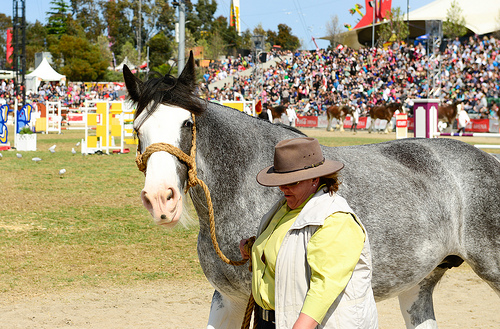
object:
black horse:
[120, 49, 499, 329]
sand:
[97, 296, 191, 317]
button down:
[240, 187, 381, 328]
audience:
[0, 34, 498, 120]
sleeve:
[299, 212, 367, 325]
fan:
[7, 34, 499, 118]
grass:
[0, 147, 135, 329]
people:
[456, 107, 471, 137]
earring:
[312, 184, 316, 186]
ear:
[311, 178, 320, 187]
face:
[484, 87, 488, 93]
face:
[491, 50, 495, 56]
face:
[492, 102, 500, 112]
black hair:
[125, 49, 208, 115]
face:
[132, 91, 195, 228]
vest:
[245, 184, 382, 329]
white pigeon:
[59, 169, 67, 175]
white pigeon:
[31, 157, 41, 161]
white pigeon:
[15, 152, 22, 158]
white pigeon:
[71, 148, 77, 154]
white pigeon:
[49, 145, 56, 153]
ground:
[1, 284, 205, 329]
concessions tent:
[26, 57, 67, 96]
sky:
[252, 0, 334, 21]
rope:
[134, 112, 252, 275]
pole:
[120, 98, 125, 153]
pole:
[106, 99, 110, 154]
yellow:
[97, 124, 123, 137]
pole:
[84, 97, 87, 148]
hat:
[255, 136, 345, 187]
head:
[278, 176, 321, 209]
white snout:
[141, 152, 183, 224]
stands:
[193, 35, 499, 118]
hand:
[239, 236, 257, 256]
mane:
[145, 55, 207, 115]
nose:
[142, 185, 177, 227]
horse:
[115, 49, 500, 329]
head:
[121, 50, 206, 226]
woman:
[232, 128, 372, 327]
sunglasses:
[284, 181, 300, 186]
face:
[277, 179, 314, 210]